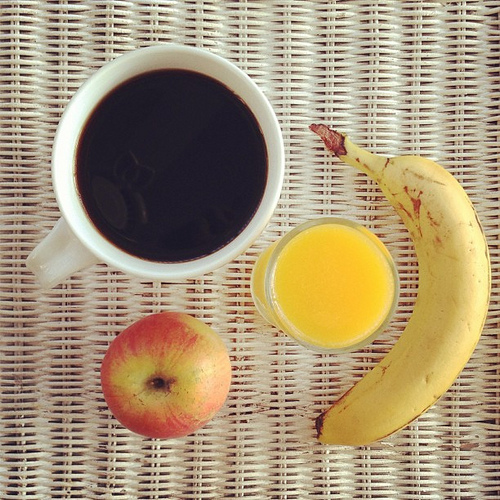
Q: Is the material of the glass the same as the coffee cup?
A: Yes, both the glass and the coffee cup are made of glass.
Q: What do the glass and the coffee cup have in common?
A: The material, both the glass and the coffee cup are glass.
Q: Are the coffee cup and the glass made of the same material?
A: Yes, both the coffee cup and the glass are made of glass.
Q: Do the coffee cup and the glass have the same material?
A: Yes, both the coffee cup and the glass are made of glass.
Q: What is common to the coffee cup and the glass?
A: The material, both the coffee cup and the glass are glass.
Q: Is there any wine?
A: No, there is no wine.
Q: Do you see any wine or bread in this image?
A: No, there are no wine or breads.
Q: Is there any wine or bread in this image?
A: No, there are no wine or breads.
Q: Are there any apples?
A: Yes, there is an apple.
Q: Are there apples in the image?
A: Yes, there is an apple.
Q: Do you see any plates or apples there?
A: Yes, there is an apple.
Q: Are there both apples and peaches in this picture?
A: No, there is an apple but no peaches.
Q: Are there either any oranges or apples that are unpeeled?
A: Yes, the apple is unpeeled.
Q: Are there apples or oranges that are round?
A: Yes, the apple is round.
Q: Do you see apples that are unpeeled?
A: Yes, there is an unpeeled apple.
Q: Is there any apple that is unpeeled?
A: Yes, there is an apple that is unpeeled.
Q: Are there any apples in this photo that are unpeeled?
A: Yes, there is an apple that is unpeeled.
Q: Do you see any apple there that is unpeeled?
A: Yes, there is an apple that is unpeeled.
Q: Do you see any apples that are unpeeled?
A: Yes, there is an apple that is unpeeled.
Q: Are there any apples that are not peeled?
A: Yes, there is a unpeeled apple.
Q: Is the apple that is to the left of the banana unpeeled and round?
A: Yes, the apple is unpeeled and round.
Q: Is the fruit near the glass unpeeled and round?
A: Yes, the apple is unpeeled and round.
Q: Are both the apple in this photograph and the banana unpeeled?
A: Yes, both the apple and the banana are unpeeled.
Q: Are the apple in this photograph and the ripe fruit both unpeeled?
A: Yes, both the apple and the banana are unpeeled.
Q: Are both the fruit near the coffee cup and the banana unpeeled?
A: Yes, both the apple and the banana are unpeeled.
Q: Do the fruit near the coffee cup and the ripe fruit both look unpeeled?
A: Yes, both the apple and the banana are unpeeled.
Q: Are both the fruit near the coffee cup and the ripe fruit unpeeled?
A: Yes, both the apple and the banana are unpeeled.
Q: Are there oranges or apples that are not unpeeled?
A: No, there is an apple but it is unpeeled.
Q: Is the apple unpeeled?
A: Yes, the apple is unpeeled.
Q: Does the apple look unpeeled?
A: Yes, the apple is unpeeled.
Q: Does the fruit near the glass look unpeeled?
A: Yes, the apple is unpeeled.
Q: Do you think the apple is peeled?
A: No, the apple is unpeeled.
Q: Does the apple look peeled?
A: No, the apple is unpeeled.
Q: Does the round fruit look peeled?
A: No, the apple is unpeeled.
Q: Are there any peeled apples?
A: No, there is an apple but it is unpeeled.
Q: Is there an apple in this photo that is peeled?
A: No, there is an apple but it is unpeeled.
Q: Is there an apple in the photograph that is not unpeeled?
A: No, there is an apple but it is unpeeled.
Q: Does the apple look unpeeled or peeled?
A: The apple is unpeeled.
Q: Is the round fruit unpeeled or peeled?
A: The apple is unpeeled.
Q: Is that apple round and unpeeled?
A: Yes, the apple is round and unpeeled.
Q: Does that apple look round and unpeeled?
A: Yes, the apple is round and unpeeled.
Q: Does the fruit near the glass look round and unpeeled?
A: Yes, the apple is round and unpeeled.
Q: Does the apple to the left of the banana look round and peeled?
A: No, the apple is round but unpeeled.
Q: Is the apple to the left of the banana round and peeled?
A: No, the apple is round but unpeeled.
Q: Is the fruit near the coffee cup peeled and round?
A: No, the apple is round but unpeeled.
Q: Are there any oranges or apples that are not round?
A: No, there is an apple but it is round.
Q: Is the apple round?
A: Yes, the apple is round.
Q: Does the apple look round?
A: Yes, the apple is round.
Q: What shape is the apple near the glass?
A: The apple is round.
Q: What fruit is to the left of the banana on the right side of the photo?
A: The fruit is an apple.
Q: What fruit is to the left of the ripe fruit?
A: The fruit is an apple.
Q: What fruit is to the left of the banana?
A: The fruit is an apple.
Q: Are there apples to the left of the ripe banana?
A: Yes, there is an apple to the left of the banana.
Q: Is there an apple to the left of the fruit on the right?
A: Yes, there is an apple to the left of the banana.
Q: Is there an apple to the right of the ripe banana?
A: No, the apple is to the left of the banana.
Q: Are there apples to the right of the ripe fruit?
A: No, the apple is to the left of the banana.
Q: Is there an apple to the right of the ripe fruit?
A: No, the apple is to the left of the banana.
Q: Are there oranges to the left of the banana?
A: No, there is an apple to the left of the banana.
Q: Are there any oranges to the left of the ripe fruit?
A: No, there is an apple to the left of the banana.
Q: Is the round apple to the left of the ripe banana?
A: Yes, the apple is to the left of the banana.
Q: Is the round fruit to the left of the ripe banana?
A: Yes, the apple is to the left of the banana.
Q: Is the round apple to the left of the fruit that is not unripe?
A: Yes, the apple is to the left of the banana.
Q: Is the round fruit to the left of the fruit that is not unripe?
A: Yes, the apple is to the left of the banana.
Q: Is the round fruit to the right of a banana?
A: No, the apple is to the left of a banana.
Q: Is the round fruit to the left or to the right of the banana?
A: The apple is to the left of the banana.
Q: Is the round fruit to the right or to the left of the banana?
A: The apple is to the left of the banana.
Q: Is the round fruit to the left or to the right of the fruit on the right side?
A: The apple is to the left of the banana.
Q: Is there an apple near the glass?
A: Yes, there is an apple near the glass.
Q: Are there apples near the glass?
A: Yes, there is an apple near the glass.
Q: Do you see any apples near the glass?
A: Yes, there is an apple near the glass.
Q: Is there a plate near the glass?
A: No, there is an apple near the glass.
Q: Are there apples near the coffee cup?
A: Yes, there is an apple near the coffee cup.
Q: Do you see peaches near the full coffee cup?
A: No, there is an apple near the coffee cup.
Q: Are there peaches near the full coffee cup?
A: No, there is an apple near the coffee cup.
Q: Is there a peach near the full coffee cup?
A: No, there is an apple near the coffee cup.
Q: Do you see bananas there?
A: Yes, there is a banana.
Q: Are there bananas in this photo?
A: Yes, there is a banana.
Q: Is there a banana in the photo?
A: Yes, there is a banana.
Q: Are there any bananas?
A: Yes, there is a banana.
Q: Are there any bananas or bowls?
A: Yes, there is a banana.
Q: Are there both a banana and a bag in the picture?
A: No, there is a banana but no bags.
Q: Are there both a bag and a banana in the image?
A: No, there is a banana but no bags.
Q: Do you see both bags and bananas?
A: No, there is a banana but no bags.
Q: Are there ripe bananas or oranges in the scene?
A: Yes, there is a ripe banana.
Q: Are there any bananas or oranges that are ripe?
A: Yes, the banana is ripe.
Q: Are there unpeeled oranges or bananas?
A: Yes, there is an unpeeled banana.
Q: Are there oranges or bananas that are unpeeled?
A: Yes, the banana is unpeeled.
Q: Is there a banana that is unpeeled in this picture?
A: Yes, there is an unpeeled banana.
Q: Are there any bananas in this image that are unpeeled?
A: Yes, there is a banana that is unpeeled.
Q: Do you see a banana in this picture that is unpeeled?
A: Yes, there is a banana that is unpeeled.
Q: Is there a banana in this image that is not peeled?
A: Yes, there is a unpeeled banana.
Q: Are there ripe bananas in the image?
A: Yes, there is a ripe banana.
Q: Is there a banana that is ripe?
A: Yes, there is a banana that is ripe.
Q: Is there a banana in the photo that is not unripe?
A: Yes, there is an ripe banana.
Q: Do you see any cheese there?
A: No, there is no cheese.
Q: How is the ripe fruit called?
A: The fruit is a banana.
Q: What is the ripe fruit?
A: The fruit is a banana.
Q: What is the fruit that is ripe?
A: The fruit is a banana.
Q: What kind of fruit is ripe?
A: The fruit is a banana.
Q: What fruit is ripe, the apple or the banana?
A: The banana is ripe.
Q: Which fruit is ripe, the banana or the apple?
A: The banana is ripe.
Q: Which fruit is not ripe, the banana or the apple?
A: The apple is not ripe.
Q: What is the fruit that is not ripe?
A: The fruit is an apple.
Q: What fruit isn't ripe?
A: The fruit is an apple.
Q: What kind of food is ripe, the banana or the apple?
A: The banana is ripe.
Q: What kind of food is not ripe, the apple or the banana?
A: The apple is not ripe.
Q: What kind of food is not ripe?
A: The food is an apple.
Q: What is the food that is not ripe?
A: The food is an apple.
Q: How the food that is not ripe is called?
A: The food is an apple.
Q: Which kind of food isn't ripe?
A: The food is an apple.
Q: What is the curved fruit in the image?
A: The fruit is a banana.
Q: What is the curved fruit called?
A: The fruit is a banana.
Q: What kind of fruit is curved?
A: The fruit is a banana.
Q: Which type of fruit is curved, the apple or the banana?
A: The banana is curved.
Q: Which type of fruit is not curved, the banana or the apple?
A: The apple is not curved.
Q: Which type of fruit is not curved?
A: The fruit is an apple.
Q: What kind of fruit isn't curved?
A: The fruit is an apple.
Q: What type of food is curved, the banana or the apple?
A: The banana is curved.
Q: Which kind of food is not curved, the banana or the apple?
A: The apple is not curved.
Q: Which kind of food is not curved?
A: The food is an apple.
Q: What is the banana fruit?
A: The fruit is a banana.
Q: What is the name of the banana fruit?
A: The fruit is a banana.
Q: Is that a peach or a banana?
A: That is a banana.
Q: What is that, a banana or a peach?
A: That is a banana.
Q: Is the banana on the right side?
A: Yes, the banana is on the right of the image.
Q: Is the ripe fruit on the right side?
A: Yes, the banana is on the right of the image.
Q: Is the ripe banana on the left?
A: No, the banana is on the right of the image.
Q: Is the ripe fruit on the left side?
A: No, the banana is on the right of the image.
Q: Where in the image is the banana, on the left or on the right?
A: The banana is on the right of the image.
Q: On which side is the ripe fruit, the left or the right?
A: The banana is on the right of the image.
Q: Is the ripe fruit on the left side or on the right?
A: The banana is on the right of the image.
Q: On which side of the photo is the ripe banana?
A: The banana is on the right of the image.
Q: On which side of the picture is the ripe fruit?
A: The banana is on the right of the image.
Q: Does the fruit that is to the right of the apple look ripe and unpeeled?
A: Yes, the banana is ripe and unpeeled.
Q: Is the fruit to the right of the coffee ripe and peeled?
A: No, the banana is ripe but unpeeled.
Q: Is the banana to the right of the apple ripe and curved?
A: Yes, the banana is ripe and curved.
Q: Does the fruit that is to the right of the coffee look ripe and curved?
A: Yes, the banana is ripe and curved.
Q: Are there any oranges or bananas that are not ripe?
A: No, there is a banana but it is ripe.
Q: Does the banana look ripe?
A: Yes, the banana is ripe.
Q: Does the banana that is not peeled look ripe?
A: Yes, the banana is ripe.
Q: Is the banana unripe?
A: No, the banana is ripe.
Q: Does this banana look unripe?
A: No, the banana is ripe.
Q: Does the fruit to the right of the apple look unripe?
A: No, the banana is ripe.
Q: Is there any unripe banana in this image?
A: No, there is a banana but it is ripe.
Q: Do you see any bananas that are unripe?
A: No, there is a banana but it is ripe.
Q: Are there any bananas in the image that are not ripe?
A: No, there is a banana but it is ripe.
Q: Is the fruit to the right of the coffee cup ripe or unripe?
A: The banana is ripe.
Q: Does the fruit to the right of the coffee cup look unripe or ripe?
A: The banana is ripe.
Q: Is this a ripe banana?
A: Yes, this is a ripe banana.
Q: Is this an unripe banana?
A: No, this is a ripe banana.